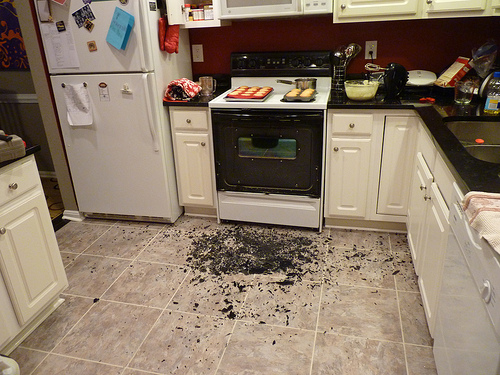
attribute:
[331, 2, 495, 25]
cabinets — wooden, white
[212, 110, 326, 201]
oven — black, white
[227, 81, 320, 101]
food — numerous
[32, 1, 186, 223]
fridge — white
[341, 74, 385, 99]
bowl — glass, empty, full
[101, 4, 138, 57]
paper — hanging, blue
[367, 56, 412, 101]
mixer — black, blackj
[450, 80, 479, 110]
cup — clear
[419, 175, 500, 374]
dishwasher — white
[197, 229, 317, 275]
stuff — black, dirty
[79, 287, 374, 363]
floor — tiled